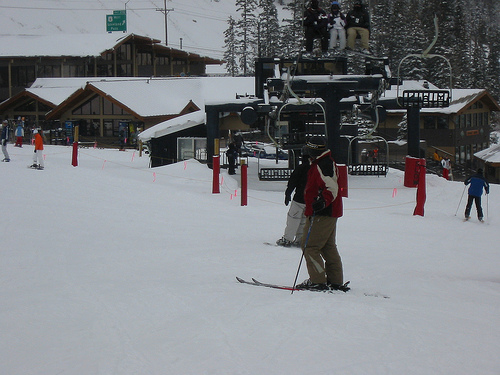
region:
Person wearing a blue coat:
[439, 156, 498, 233]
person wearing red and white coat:
[282, 133, 356, 295]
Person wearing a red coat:
[27, 123, 49, 178]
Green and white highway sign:
[94, 9, 139, 46]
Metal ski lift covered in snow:
[388, 33, 464, 117]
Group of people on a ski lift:
[286, 0, 389, 69]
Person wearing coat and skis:
[231, 134, 363, 307]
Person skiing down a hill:
[444, 153, 494, 233]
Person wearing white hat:
[17, 120, 48, 177]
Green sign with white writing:
[90, 6, 133, 43]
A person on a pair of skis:
[272, 125, 390, 325]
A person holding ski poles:
[262, 137, 363, 317]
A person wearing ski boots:
[251, 145, 368, 317]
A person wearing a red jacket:
[275, 130, 361, 300]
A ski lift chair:
[330, 81, 410, 211]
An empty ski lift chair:
[251, 136, 306, 196]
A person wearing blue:
[440, 150, 487, 241]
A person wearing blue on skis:
[455, 156, 495, 222]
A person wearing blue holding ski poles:
[460, 156, 490, 231]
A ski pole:
[282, 227, 322, 322]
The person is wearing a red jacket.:
[285, 141, 357, 221]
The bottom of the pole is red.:
[210, 154, 235, 199]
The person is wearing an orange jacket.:
[28, 129, 50, 176]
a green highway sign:
[85, 3, 144, 40]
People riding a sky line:
[284, 3, 398, 82]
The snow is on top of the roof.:
[115, 68, 264, 131]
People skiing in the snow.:
[256, 141, 359, 287]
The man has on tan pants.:
[272, 214, 362, 301]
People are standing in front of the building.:
[10, 116, 142, 188]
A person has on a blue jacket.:
[458, 162, 496, 242]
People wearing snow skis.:
[4, 115, 499, 293]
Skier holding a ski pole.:
[233, 134, 350, 294]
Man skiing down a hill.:
[452, 166, 494, 224]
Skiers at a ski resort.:
[0, 2, 498, 352]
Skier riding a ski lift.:
[300, 1, 372, 58]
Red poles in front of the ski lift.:
[211, 155, 247, 207]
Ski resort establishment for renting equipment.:
[2, 73, 257, 148]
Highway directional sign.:
[105, 8, 127, 33]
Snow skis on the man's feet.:
[235, 273, 353, 290]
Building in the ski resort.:
[342, 83, 498, 180]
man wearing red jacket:
[234, 120, 382, 301]